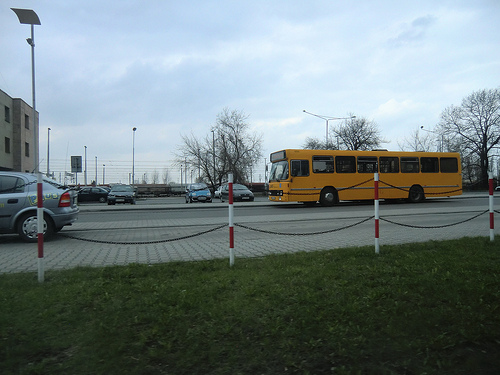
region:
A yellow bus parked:
[262, 140, 474, 205]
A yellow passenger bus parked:
[261, 139, 469, 209]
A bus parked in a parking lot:
[238, 144, 475, 206]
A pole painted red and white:
[216, 165, 241, 260]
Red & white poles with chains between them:
[232, 166, 390, 263]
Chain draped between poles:
[230, 216, 376, 243]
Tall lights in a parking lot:
[125, 116, 140, 182]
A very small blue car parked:
[181, 181, 213, 202]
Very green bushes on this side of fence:
[300, 263, 481, 360]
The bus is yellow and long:
[261, 146, 471, 199]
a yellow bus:
[264, 148, 464, 208]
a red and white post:
[33, 178, 47, 286]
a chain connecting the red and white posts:
[0, 176, 499, 198]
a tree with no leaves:
[176, 106, 266, 183]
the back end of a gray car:
[0, 170, 77, 244]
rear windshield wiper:
[40, 176, 68, 191]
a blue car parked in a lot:
[185, 180, 211, 203]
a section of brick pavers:
[61, 245, 226, 258]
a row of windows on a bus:
[289, 154, 461, 177]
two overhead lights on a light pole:
[302, 107, 359, 149]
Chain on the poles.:
[52, 217, 499, 252]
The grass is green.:
[256, 270, 445, 354]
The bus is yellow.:
[265, 138, 470, 205]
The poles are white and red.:
[28, 189, 499, 266]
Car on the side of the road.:
[0, 169, 88, 238]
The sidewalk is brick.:
[41, 233, 248, 262]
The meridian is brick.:
[81, 211, 281, 229]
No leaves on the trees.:
[194, 116, 261, 186]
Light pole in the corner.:
[11, 2, 51, 178]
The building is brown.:
[1, 95, 44, 183]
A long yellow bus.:
[259, 148, 464, 208]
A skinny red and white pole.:
[221, 171, 240, 269]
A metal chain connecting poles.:
[0, 206, 499, 245]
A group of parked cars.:
[69, 178, 255, 207]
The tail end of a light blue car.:
[0, 170, 80, 237]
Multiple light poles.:
[41, 121, 197, 186]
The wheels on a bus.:
[313, 182, 429, 204]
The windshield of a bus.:
[266, 159, 294, 182]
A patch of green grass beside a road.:
[1, 230, 498, 373]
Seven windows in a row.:
[308, 152, 459, 179]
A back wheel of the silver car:
[15, 214, 53, 245]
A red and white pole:
[222, 172, 239, 267]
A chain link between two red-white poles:
[229, 212, 379, 239]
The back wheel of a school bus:
[402, 180, 429, 205]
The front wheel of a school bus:
[318, 187, 340, 207]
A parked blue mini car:
[182, 179, 212, 206]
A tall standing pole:
[130, 124, 136, 184]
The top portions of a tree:
[442, 90, 499, 143]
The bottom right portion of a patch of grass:
[422, 254, 497, 374]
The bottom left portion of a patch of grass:
[0, 292, 126, 374]